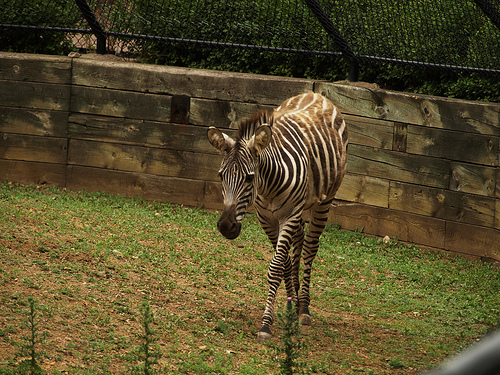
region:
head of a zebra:
[203, 116, 280, 238]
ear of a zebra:
[197, 111, 233, 157]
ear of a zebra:
[243, 128, 280, 160]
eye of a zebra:
[240, 172, 256, 184]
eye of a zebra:
[212, 160, 229, 180]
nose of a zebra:
[215, 216, 247, 231]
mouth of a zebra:
[210, 225, 251, 247]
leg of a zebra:
[249, 215, 303, 334]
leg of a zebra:
[293, 208, 342, 318]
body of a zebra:
[265, 52, 391, 214]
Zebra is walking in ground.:
[185, 93, 365, 338]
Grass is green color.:
[44, 205, 254, 281]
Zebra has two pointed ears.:
[203, 123, 278, 153]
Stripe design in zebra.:
[277, 108, 344, 215]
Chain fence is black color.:
[66, 0, 476, 76]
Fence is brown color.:
[6, 60, 473, 227]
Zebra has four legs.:
[246, 230, 333, 347]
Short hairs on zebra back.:
[226, 101, 288, 146]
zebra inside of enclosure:
[0, 15, 495, 366]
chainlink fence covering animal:
[3, 1, 493, 82]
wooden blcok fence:
[0, 47, 487, 262]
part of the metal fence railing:
[381, 322, 497, 372]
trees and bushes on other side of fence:
[0, 2, 491, 93]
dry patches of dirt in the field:
[2, 205, 365, 371]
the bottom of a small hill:
[5, 155, 285, 370]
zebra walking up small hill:
[195, 95, 377, 341]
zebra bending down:
[162, 88, 351, 328]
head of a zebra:
[198, 115, 279, 242]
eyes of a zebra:
[209, 165, 265, 187]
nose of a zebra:
[210, 199, 239, 237]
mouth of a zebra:
[217, 226, 243, 248]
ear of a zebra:
[199, 119, 231, 151]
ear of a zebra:
[249, 123, 280, 169]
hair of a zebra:
[228, 113, 286, 131]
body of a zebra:
[258, 80, 365, 203]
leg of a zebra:
[259, 237, 287, 344]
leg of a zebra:
[292, 218, 344, 336]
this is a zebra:
[197, 70, 403, 341]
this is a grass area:
[49, 195, 224, 316]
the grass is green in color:
[379, 273, 451, 328]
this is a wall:
[389, 98, 499, 248]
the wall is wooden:
[393, 125, 455, 223]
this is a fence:
[357, 13, 488, 88]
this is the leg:
[255, 217, 296, 372]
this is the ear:
[249, 118, 281, 153]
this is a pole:
[316, 9, 349, 63]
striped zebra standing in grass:
[206, 89, 350, 339]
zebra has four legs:
[253, 200, 337, 341]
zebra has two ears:
[203, 119, 273, 156]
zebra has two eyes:
[216, 167, 256, 186]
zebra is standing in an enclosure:
[2, 4, 498, 374]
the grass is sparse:
[1, 183, 499, 373]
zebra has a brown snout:
[217, 207, 245, 240]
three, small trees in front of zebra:
[20, 294, 321, 371]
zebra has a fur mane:
[229, 106, 276, 167]